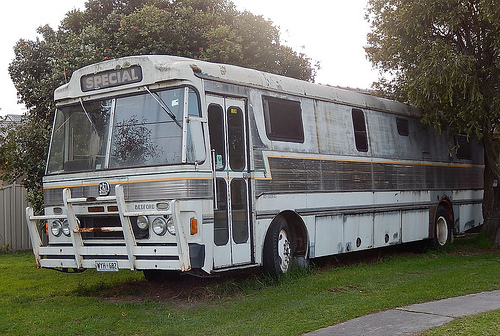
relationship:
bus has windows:
[22, 49, 471, 278] [253, 95, 438, 169]